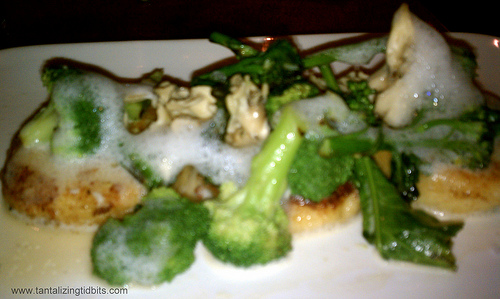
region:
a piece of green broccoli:
[192, 102, 308, 273]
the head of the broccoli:
[196, 193, 301, 270]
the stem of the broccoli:
[238, 108, 308, 203]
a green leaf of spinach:
[343, 151, 464, 273]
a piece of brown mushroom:
[362, 4, 444, 131]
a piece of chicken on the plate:
[0, 86, 497, 249]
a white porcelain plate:
[1, 25, 498, 295]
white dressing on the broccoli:
[89, 217, 179, 281]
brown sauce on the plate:
[1, 201, 101, 291]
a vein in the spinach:
[358, 155, 388, 259]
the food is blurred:
[67, 61, 361, 283]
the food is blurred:
[196, 134, 317, 258]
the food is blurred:
[50, 24, 262, 232]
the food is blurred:
[107, 101, 319, 249]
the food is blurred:
[123, 114, 260, 226]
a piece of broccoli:
[197, 100, 319, 277]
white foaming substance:
[374, 20, 472, 130]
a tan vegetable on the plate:
[207, 67, 281, 148]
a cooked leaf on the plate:
[334, 131, 481, 285]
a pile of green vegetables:
[9, 7, 494, 278]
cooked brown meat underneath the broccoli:
[277, 178, 384, 233]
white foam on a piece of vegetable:
[22, 48, 133, 152]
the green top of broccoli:
[285, 135, 361, 202]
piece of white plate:
[22, 20, 187, 71]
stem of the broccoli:
[312, 120, 380, 157]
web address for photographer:
[9, 284, 132, 297]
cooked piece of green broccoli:
[213, 132, 298, 272]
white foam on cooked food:
[141, 134, 195, 161]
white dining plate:
[110, 39, 148, 69]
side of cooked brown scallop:
[17, 164, 107, 221]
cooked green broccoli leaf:
[352, 152, 458, 278]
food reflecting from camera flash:
[194, 46, 224, 70]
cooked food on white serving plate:
[47, 35, 485, 262]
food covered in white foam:
[103, 92, 258, 222]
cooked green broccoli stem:
[301, 31, 356, 78]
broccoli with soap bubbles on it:
[43, 65, 489, 197]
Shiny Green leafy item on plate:
[343, 150, 468, 280]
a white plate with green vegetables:
[7, 29, 499, 254]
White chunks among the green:
[156, 73, 269, 159]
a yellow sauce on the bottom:
[3, 156, 486, 259]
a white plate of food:
[13, 36, 498, 295]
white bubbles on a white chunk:
[359, 18, 477, 170]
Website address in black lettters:
[6, 280, 136, 297]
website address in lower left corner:
[9, 279, 131, 297]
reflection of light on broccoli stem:
[245, 121, 298, 223]